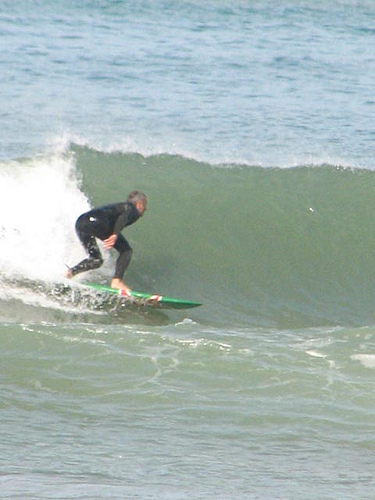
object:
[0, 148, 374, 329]
water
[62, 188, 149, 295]
surfer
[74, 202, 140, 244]
lowered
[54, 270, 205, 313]
surfboard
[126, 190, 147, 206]
grey hair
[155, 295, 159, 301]
red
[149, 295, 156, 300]
white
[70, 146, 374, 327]
wave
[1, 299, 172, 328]
shadow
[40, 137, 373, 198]
high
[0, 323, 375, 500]
water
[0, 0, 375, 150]
water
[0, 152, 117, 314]
foam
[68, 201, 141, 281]
clothing